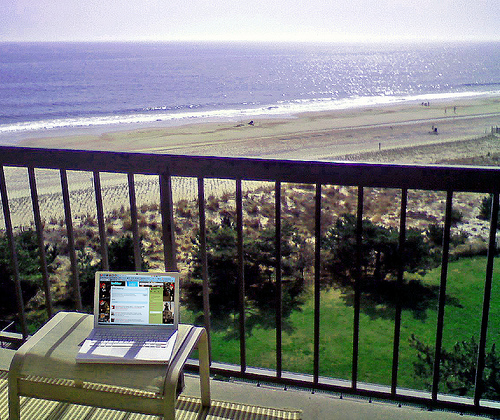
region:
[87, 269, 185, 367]
A white laptop displaying a webpage.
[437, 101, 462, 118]
Two people walking on the beach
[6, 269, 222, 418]
A foot rest supporting a laptop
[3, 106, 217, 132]
Ocean waves meeting the shore.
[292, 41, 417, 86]
The ocean reflecting sunlight.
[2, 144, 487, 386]
Balcony overlooking yard and beach.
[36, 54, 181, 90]
Blue looking ocean water.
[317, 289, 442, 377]
Green grass with a tree shadow.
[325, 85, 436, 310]
Tree growing by the beach.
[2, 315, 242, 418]
Striped carpet on a balcony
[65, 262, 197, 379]
A laptop computer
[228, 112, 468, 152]
Sand on a beach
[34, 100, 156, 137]
Waves breaking on a beach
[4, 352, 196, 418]
A small bench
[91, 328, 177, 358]
The keyboard part of a laptop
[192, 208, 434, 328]
Some scrubby bushes along a beach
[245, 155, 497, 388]
A fence on a balcony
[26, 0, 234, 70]
The sky meeting the ocean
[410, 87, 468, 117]
People walking along a beach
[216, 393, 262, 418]
A striped rug on a balcony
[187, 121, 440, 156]
The beach near the ocean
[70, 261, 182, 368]
A white laptop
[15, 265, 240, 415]
The laptop on a table.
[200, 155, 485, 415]
A fence over looking the beach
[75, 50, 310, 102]
The ocean reflecting the sun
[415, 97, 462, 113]
People on the beach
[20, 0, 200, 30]
A clear blue sky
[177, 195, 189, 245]
Shrubs on the sand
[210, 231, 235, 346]
A tree near the beach.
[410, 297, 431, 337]
The lawn near the beach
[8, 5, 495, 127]
The sun is bright.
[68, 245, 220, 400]
A laptop is on a foot stool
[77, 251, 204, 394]
The laptop is open and on.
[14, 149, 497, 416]
The railing is metal and block.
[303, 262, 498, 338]
The lawn is green with grass.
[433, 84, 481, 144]
There are two people on the beach.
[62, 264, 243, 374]
The laptop is white in color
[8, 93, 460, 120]
The ocean is cresting with white waves.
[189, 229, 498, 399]
There are green trees below.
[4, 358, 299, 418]
There is a beige rug on the balcony.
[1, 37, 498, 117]
ocean water is blue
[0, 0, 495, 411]
balcony railing in front of beach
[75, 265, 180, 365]
white laptop is open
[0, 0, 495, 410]
balcony overlooking beach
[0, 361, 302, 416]
striped carpet on balcony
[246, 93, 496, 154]
people on beach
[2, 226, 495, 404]
bright green grass and dark green trees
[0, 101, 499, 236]
sand on beach is tan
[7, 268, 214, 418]
laptop on small table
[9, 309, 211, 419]
table on balcony